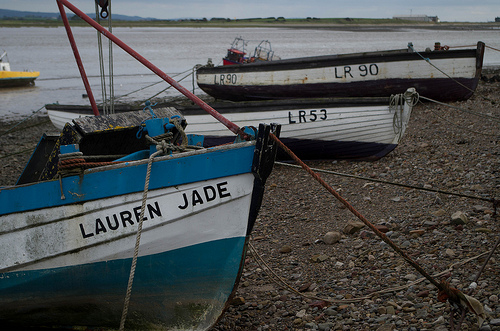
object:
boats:
[46, 86, 418, 162]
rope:
[138, 189, 148, 214]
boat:
[0, 122, 283, 330]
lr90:
[334, 63, 379, 78]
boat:
[197, 40, 487, 103]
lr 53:
[287, 109, 328, 125]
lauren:
[78, 202, 161, 239]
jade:
[178, 181, 234, 210]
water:
[138, 29, 203, 51]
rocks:
[465, 98, 485, 111]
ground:
[289, 227, 352, 274]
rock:
[434, 207, 473, 227]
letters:
[217, 181, 232, 198]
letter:
[289, 111, 297, 124]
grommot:
[86, 4, 118, 29]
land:
[376, 318, 426, 331]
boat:
[0, 50, 41, 87]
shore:
[10, 108, 32, 118]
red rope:
[299, 159, 346, 205]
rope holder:
[46, 105, 207, 166]